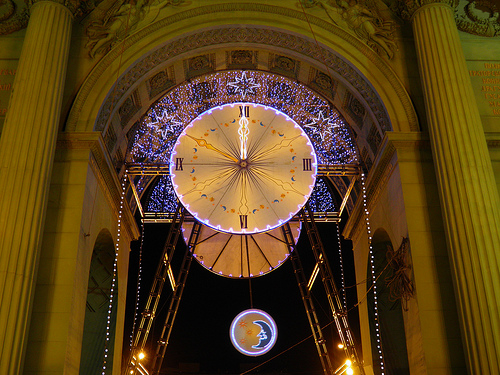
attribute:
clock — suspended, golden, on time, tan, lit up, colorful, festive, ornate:
[169, 102, 319, 234]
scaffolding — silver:
[119, 203, 368, 375]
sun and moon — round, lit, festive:
[228, 308, 280, 358]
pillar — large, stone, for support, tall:
[401, 1, 499, 374]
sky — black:
[120, 210, 364, 374]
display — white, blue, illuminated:
[131, 67, 361, 165]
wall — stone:
[39, 0, 450, 270]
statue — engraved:
[85, 0, 194, 59]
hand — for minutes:
[184, 133, 239, 164]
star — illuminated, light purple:
[230, 72, 263, 101]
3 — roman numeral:
[300, 157, 315, 173]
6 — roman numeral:
[238, 211, 253, 230]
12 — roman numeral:
[237, 104, 251, 120]